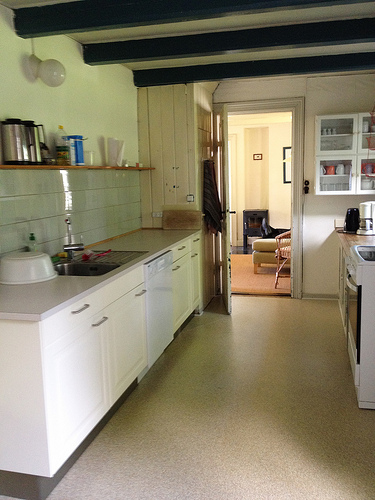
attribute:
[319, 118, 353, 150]
glass — white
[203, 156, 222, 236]
towel — hanging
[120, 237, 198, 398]
dishwasher — built-in, brand-name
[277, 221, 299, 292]
chair — brown, wooden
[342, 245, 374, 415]
stove — white, black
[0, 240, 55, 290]
bowl — white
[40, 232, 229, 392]
cabinetry — white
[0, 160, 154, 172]
shelf — brown